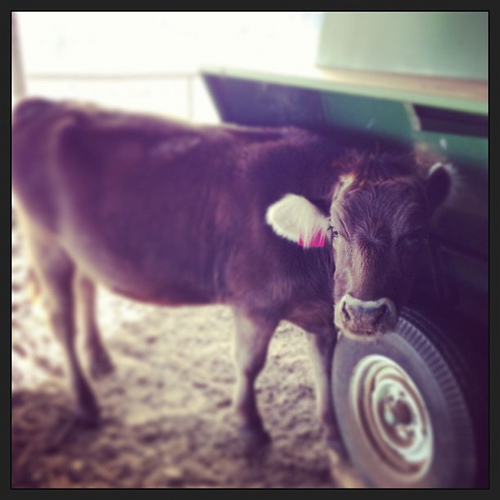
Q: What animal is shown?
A: Cow.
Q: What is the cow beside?
A: A tractor.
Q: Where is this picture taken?
A: A barn.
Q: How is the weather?
A: Sunny.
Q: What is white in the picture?
A: The sky.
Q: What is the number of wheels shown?
A: One.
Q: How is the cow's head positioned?
A: It is turned.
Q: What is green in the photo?
A: The tractor.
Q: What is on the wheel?
A: Tire.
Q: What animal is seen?
A: Cow.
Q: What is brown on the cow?
A: Fur.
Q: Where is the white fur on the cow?
A: Ear.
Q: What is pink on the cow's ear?
A: Tag.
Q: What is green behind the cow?
A: Truck.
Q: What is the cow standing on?
A: Dirt.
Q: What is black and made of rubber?
A: Tire.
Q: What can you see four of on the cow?
A: Legs.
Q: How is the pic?
A: Blurry.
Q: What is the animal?
A: Cow.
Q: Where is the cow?
A: Next to the vehicle.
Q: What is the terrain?
A: Soil.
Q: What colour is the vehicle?
A: Green.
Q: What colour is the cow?
A: Brown.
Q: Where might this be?
A: Farm.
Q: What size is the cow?
A: Medium.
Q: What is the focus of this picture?
A: A calf.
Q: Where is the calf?
A: In a barn.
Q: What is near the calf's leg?
A: A tire.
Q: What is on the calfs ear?
A: A red tag.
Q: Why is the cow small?
A: It is a baby.